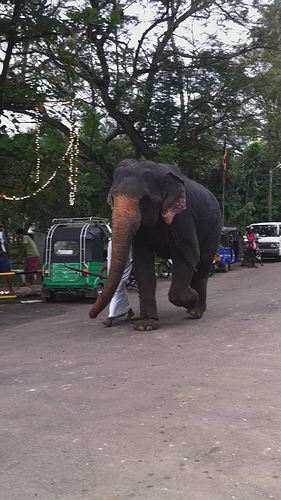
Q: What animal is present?
A: Elephant.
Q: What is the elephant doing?
A: Walking.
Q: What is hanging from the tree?
A: Lights.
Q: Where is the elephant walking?
A: Pavement.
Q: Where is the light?
A: In trees.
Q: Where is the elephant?
A: On road.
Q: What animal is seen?
A: Elephant.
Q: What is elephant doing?
A: Walking.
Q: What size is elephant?
A: Large.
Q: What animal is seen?
A: Elephant.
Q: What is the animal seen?
A: Elephant.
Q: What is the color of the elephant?
A: Grey.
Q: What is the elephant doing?
A: Walking.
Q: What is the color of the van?
A: White.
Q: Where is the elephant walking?
A: In the road.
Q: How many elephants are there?
A: One.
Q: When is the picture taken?
A: Daytime.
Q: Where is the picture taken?
A: At a zoo.